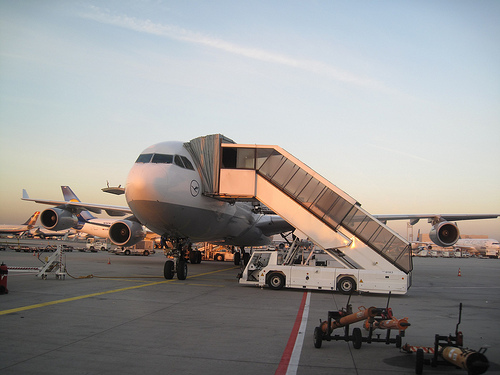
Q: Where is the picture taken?
A: Airport.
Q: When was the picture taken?
A: Daytime.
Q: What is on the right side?
A: A stair car.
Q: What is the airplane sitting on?
A: Tarmac.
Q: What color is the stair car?
A: White.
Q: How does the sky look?
A: Clear.